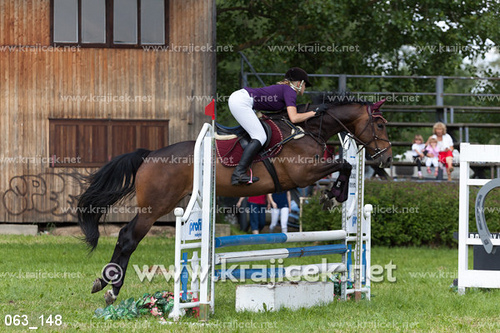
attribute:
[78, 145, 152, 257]
tail — black, horse's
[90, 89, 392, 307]
horse — jumping, brown, black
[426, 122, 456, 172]
woman — sitting, sitting down, riding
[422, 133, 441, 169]
child — sitting down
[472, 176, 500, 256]
horseshoe — half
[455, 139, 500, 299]
fence — white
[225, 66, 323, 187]
person — riding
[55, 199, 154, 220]
logo — website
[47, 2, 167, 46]
window — black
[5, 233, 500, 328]
grass — green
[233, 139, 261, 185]
riding boots — black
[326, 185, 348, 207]
hooves — horse's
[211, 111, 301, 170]
saddle — english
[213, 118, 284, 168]
blanket — horse's, maroon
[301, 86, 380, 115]
mane — black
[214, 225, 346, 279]
rails — blue, white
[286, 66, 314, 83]
helmet — black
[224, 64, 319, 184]
woman — riding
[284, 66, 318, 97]
head — woman's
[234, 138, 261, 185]
boot — balck, rider's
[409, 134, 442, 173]
kids — sitting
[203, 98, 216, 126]
flag — red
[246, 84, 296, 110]
shirt — purple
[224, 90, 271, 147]
pants — white, rider's, tight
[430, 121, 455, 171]
person — watching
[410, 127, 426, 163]
person — watching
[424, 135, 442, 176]
person — watching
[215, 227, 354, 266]
poles — blue, white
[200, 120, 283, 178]
saddle — red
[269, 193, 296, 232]
person — walking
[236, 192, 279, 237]
person — walking